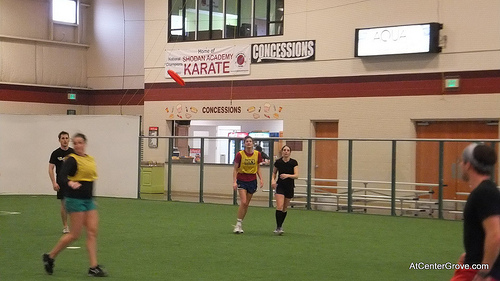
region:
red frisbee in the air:
[160, 70, 189, 87]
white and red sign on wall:
[172, 51, 252, 75]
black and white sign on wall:
[250, 39, 315, 61]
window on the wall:
[46, 0, 82, 23]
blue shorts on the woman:
[61, 195, 101, 213]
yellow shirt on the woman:
[70, 156, 103, 183]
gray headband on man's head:
[464, 141, 495, 172]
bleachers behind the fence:
[306, 173, 432, 216]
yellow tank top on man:
[235, 145, 260, 171]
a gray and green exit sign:
[65, 90, 81, 100]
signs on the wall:
[182, 33, 310, 69]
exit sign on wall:
[430, 71, 467, 90]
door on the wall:
[302, 115, 345, 200]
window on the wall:
[150, 114, 230, 161]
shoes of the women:
[225, 220, 287, 234]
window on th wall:
[50, 0, 88, 33]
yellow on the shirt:
[80, 159, 93, 175]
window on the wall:
[133, 3, 288, 38]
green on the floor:
[210, 253, 270, 278]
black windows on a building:
[167, 1, 284, 39]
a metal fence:
[141, 137, 499, 214]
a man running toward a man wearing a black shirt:
[231, 139, 263, 237]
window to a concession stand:
[171, 120, 281, 162]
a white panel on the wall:
[146, 127, 159, 147]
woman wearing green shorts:
[63, 196, 95, 211]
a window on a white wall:
[50, 0, 78, 22]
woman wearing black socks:
[274, 206, 287, 227]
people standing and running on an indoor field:
[43, 130, 498, 279]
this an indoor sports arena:
[32, 11, 464, 248]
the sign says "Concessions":
[247, 38, 319, 70]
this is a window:
[152, 6, 314, 47]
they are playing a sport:
[47, 97, 454, 274]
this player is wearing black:
[268, 150, 311, 210]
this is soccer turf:
[117, 201, 234, 277]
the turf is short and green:
[123, 191, 224, 277]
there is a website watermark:
[394, 244, 462, 278]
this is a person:
[227, 129, 266, 242]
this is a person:
[25, 128, 104, 272]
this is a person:
[224, 127, 276, 246]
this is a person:
[268, 140, 310, 237]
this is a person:
[35, 116, 82, 206]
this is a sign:
[167, 39, 248, 77]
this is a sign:
[251, 34, 328, 76]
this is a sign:
[193, 101, 261, 130]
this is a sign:
[351, 24, 426, 69]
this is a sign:
[242, 90, 292, 124]